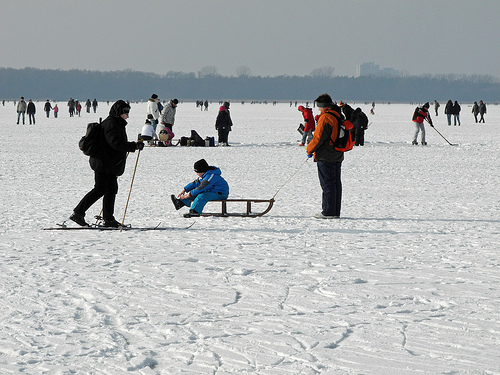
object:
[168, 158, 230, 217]
boy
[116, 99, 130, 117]
hair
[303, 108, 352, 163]
jacket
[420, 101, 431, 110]
hat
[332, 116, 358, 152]
back pack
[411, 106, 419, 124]
back pack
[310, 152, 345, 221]
pants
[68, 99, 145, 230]
people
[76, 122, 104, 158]
backpack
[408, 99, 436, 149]
man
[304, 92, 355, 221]
woman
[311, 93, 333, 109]
hair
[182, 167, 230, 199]
coat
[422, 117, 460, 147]
hockey stick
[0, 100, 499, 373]
ground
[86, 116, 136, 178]
jacket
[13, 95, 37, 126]
couple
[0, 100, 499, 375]
snow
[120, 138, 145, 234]
hockey stick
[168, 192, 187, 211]
shoe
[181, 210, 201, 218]
shoe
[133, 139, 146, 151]
hand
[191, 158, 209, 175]
black hat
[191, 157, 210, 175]
head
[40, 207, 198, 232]
skies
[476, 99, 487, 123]
people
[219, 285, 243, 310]
cracks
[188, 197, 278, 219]
sled